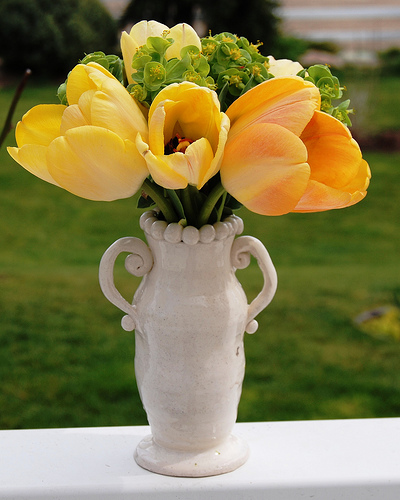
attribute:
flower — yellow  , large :
[216, 71, 373, 217]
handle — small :
[96, 235, 149, 327]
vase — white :
[92, 216, 279, 477]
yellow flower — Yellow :
[113, 15, 203, 83]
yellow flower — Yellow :
[264, 55, 305, 80]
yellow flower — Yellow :
[136, 77, 232, 188]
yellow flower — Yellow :
[7, 60, 151, 203]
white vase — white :
[96, 204, 282, 478]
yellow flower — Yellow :
[223, 81, 371, 219]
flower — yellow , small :
[140, 80, 233, 195]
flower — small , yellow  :
[223, 74, 379, 215]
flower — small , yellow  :
[2, 60, 147, 209]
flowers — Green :
[127, 28, 272, 93]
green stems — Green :
[141, 187, 229, 221]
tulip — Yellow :
[219, 74, 372, 216]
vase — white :
[100, 200, 283, 475]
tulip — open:
[130, 75, 238, 197]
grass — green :
[0, 75, 399, 427]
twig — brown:
[1, 68, 34, 149]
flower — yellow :
[157, 19, 197, 57]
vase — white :
[133, 223, 254, 499]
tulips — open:
[69, 58, 368, 183]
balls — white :
[140, 208, 244, 245]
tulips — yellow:
[2, 14, 376, 229]